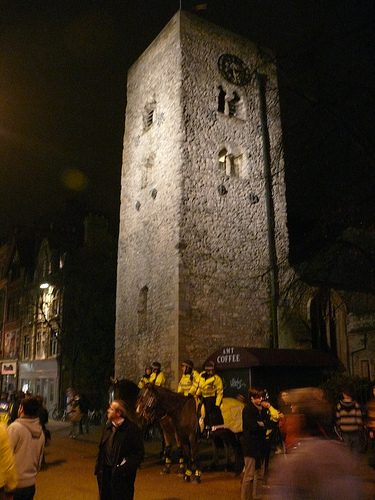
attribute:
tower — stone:
[107, 6, 293, 389]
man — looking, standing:
[92, 399, 141, 498]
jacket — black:
[92, 418, 145, 478]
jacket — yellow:
[189, 373, 223, 405]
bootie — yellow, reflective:
[193, 468, 203, 480]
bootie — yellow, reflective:
[183, 468, 195, 478]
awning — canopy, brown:
[199, 342, 349, 375]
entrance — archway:
[308, 285, 352, 376]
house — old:
[19, 211, 117, 412]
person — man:
[7, 392, 49, 498]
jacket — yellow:
[146, 370, 167, 386]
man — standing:
[238, 385, 270, 498]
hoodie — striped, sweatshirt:
[332, 398, 364, 431]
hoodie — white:
[6, 421, 46, 487]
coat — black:
[238, 402, 271, 458]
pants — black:
[94, 469, 135, 498]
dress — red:
[275, 416, 304, 453]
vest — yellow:
[138, 377, 150, 390]